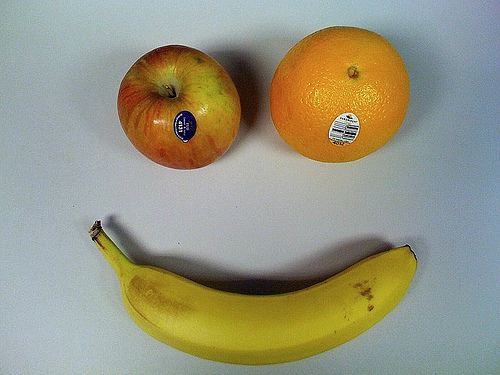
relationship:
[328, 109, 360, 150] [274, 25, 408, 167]
sticker on orange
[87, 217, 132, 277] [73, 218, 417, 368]
stem of banana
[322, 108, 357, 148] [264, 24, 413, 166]
sticker on orange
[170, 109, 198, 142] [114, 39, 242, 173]
sticker on apple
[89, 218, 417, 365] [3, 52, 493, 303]
banana in photo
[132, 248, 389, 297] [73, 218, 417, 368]
shadow of banana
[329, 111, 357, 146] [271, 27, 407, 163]
sticker on fruit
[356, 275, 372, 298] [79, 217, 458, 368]
bruises on banana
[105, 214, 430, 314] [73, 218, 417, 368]
shadow by banana